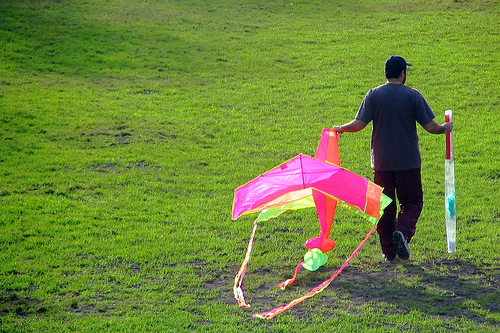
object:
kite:
[230, 128, 393, 325]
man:
[332, 56, 453, 266]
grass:
[1, 2, 499, 333]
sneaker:
[389, 229, 409, 260]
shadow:
[298, 255, 500, 325]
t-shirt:
[355, 83, 436, 173]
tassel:
[276, 262, 303, 294]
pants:
[370, 169, 425, 260]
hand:
[442, 121, 452, 134]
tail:
[230, 218, 260, 309]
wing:
[230, 150, 386, 225]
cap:
[384, 56, 413, 67]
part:
[79, 122, 146, 152]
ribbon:
[251, 223, 380, 324]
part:
[251, 305, 280, 321]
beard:
[401, 69, 407, 85]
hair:
[384, 66, 406, 79]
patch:
[88, 293, 108, 308]